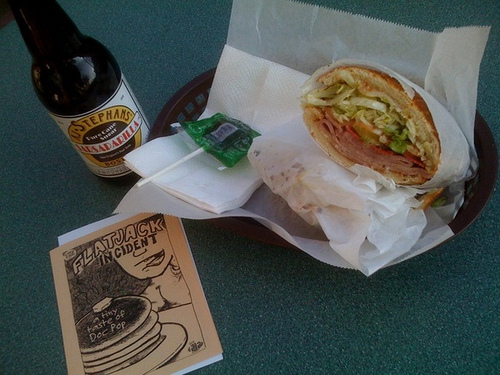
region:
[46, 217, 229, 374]
a small greeting card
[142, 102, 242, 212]
a very yummy caramel apple lollipop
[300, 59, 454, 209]
half of a sub sandwich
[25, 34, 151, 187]
a glass bottle of sasparilla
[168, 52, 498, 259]
a plastic tray for the food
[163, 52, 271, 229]
napkins to use with the food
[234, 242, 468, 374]
part of the table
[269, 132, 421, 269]
french fries under the paper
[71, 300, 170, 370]
a plate filled with pancakes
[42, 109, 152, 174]
the label on the bottle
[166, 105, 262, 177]
a green lollipop wrapper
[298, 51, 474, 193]
half of a cold cut sub sandwich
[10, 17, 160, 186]
a bottle of sarsparilla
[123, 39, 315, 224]
a lollipop on a pile of napkins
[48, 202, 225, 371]
a pamphlet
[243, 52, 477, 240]
a sandwich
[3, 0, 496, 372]
a lunch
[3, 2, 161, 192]
a brown bottle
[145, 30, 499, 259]
a basket of food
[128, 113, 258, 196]
a lollipop in a celophane wrapper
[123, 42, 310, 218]
a pile of paper napkins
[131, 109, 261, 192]
a lollipop in a wrapper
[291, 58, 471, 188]
a wrapped sandwich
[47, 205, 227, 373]
a brown paper book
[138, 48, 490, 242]
a plastic basket of food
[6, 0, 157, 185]
a glass bottle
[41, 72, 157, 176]
a label on a bottle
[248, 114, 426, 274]
wrapped food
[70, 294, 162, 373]
a picture of pancakes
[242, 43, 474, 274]
a wrapped sandwich cut in half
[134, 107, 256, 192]
a sucker with green wrapper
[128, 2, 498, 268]
this basket has food inside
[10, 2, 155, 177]
the bottle is dark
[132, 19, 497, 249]
brown basket with white paper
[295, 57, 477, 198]
this sandwish has a lot of filling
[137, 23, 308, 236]
a sucker on top of napkins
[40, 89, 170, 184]
the label is white, yellow, brown and red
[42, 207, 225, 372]
a tan booklet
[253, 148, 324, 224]
grease spots are on the paper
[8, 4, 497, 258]
Turkey sandwich and a beer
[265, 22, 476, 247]
Turkey sandwich with lettuce and tomato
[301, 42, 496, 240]
Turkey sandwich with white bread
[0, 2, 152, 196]
Bottle of beer is next to the sandwich basket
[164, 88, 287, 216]
A lollipop is in the sandwich basket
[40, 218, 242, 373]
Flyer with an illustration of pankcakes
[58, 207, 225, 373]
Illustration shows man and pancakes with a piece of butter on top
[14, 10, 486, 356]
Beer, illustration and sandwich are sitting on a table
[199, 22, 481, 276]
Sandwich is wrapped in white parchment paper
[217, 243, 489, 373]
The tabletop is bluish in color and has light blue specks